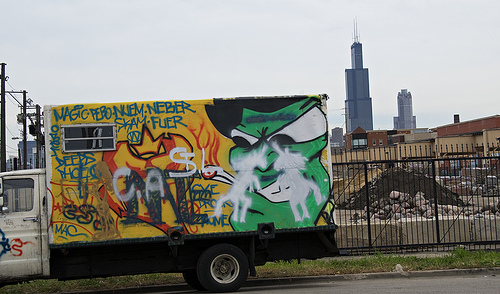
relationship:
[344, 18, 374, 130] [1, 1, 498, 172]
building in background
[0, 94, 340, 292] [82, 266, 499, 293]
truck on side of road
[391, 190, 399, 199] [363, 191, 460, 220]
rocks in pile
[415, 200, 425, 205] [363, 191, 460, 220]
rocks in pile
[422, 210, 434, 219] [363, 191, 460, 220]
rocks in pile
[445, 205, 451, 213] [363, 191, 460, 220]
rocks in pile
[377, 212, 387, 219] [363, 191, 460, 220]
rocks in pile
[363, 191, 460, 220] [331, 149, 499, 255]
pile on or side of fence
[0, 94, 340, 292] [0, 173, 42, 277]
truck has door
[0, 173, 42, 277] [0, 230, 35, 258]
door has graffitti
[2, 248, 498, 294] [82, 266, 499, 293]
grass along road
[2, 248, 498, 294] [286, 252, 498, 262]
grass along sidewalk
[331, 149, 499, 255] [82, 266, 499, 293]
fence on side of road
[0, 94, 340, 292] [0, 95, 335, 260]
truck with paint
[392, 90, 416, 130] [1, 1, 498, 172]
building in background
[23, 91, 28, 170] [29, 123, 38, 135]
pole of power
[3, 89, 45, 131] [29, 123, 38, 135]
lines of power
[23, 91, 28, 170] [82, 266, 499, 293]
pole are going down road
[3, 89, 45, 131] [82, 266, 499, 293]
lines are going down road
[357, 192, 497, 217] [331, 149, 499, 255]
pile of rock behind fence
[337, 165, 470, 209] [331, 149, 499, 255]
pile of dirt behind fence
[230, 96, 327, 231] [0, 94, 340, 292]
face on side of truck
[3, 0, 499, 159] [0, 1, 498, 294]
sky about city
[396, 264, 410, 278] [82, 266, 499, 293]
trash on side of th road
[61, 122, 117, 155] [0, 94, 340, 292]
window on side of truck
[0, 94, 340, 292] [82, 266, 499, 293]
truck on road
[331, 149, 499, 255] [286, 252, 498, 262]
fence on sidewalk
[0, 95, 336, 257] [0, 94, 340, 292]
graffiti on truck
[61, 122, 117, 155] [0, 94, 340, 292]
window on truck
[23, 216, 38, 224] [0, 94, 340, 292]
handle on truck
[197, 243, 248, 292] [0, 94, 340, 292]
tire on truck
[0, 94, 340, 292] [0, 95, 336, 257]
truck has graffiti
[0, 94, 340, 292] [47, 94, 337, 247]
truck has decoration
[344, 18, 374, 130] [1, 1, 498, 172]
building in distance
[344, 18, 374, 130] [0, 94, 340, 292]
building are behind truck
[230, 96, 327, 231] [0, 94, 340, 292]
picture in truck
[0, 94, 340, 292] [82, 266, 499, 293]
truck in road